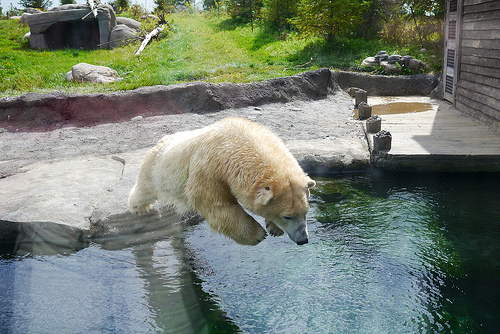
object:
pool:
[0, 155, 498, 332]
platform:
[0, 70, 374, 221]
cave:
[18, 2, 148, 54]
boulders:
[15, 0, 161, 86]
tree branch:
[135, 24, 166, 60]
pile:
[106, 8, 163, 59]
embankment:
[0, 67, 342, 117]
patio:
[351, 0, 499, 155]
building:
[436, 0, 497, 141]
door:
[440, 2, 463, 105]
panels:
[445, 20, 458, 41]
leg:
[124, 149, 159, 216]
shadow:
[126, 229, 244, 334]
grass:
[0, 0, 444, 92]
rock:
[0, 156, 205, 252]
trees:
[286, 1, 366, 44]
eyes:
[282, 215, 295, 222]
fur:
[192, 117, 289, 184]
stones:
[348, 82, 394, 152]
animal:
[124, 116, 319, 246]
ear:
[303, 177, 315, 190]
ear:
[261, 190, 273, 207]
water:
[0, 167, 499, 333]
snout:
[284, 228, 309, 246]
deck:
[344, 81, 499, 170]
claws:
[233, 226, 270, 247]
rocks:
[356, 45, 431, 72]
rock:
[60, 61, 120, 84]